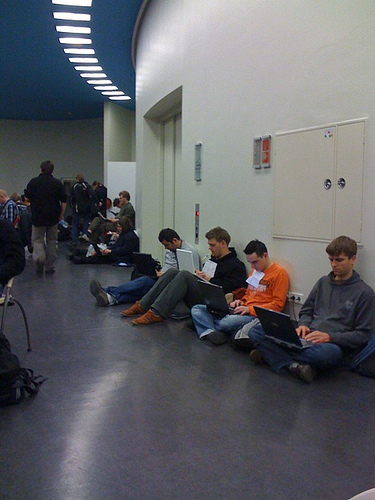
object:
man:
[89, 228, 200, 307]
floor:
[0, 240, 375, 500]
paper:
[246, 269, 266, 288]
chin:
[256, 269, 262, 272]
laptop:
[176, 248, 208, 282]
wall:
[140, 19, 374, 83]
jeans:
[106, 275, 157, 303]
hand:
[234, 306, 250, 316]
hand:
[305, 330, 330, 343]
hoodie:
[203, 246, 248, 294]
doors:
[159, 111, 183, 265]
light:
[53, 11, 91, 21]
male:
[247, 235, 374, 383]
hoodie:
[298, 268, 375, 356]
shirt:
[297, 269, 374, 349]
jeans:
[247, 325, 342, 376]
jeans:
[71, 213, 88, 243]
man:
[23, 160, 68, 275]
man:
[68, 173, 103, 248]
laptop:
[197, 279, 240, 318]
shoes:
[119, 300, 164, 326]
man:
[120, 226, 249, 327]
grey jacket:
[296, 269, 375, 349]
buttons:
[194, 203, 200, 244]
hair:
[326, 235, 358, 260]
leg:
[286, 342, 343, 370]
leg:
[248, 324, 289, 373]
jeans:
[190, 304, 256, 340]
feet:
[120, 300, 165, 327]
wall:
[173, 152, 245, 295]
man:
[191, 237, 290, 351]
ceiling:
[0, 0, 142, 122]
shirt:
[240, 260, 290, 317]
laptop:
[253, 305, 322, 350]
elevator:
[140, 85, 186, 255]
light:
[68, 57, 98, 64]